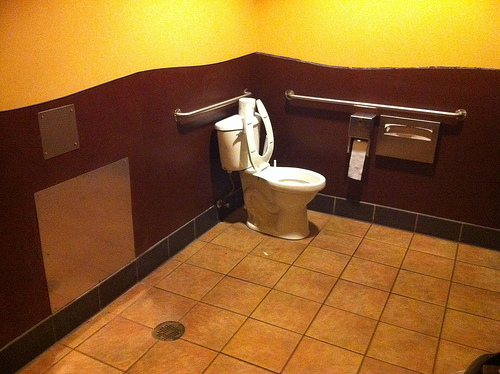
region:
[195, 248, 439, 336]
The floor is made of tile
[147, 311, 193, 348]
The drain in the ground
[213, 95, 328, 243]
The toilet is the color white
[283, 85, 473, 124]
The holding bar on the wall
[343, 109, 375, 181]
The toilet paper dispenser on the wall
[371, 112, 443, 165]
The toilet paper cover holder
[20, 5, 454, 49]
The color of the wall is yellow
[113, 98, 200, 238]
The color of the wall is brown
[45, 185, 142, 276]
The silver plate on the wall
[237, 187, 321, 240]
The bottom of the toilet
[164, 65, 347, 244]
this is a toilet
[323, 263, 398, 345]
this is a tile on the floor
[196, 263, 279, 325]
this is a tile on the floor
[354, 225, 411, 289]
this is a tile on the floor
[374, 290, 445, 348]
this is a tile on the floor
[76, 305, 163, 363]
this is a tile on the floor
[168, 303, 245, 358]
this is a tile on the floor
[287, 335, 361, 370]
this is a tile on the floor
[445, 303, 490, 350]
this is a tile on the floor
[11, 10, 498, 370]
a public restroom has a tiled floor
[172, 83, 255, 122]
a grab bar is above the toilet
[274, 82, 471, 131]
a long grab bar is near the toilet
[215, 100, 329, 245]
the toilet is white porcelain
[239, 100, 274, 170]
the seat is up on the toilet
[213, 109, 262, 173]
the water closet is on the toilet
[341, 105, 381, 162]
a metal toilet paper dispenser is on the wall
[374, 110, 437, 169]
tissue seat liner dispenser is on the wall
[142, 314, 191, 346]
a drain is in the floor of the bathroom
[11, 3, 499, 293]
the walls are painted yellow and brown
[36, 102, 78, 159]
the small petal plate on the wall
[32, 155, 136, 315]
the large metal plate on the wall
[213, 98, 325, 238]
the white toilet bowl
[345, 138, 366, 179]
the toilet paper in the dispenser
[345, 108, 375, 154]
the toilet paper metal dispenser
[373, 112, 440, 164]
the dispenser for toilet seat protector sheets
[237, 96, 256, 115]
the roll of toilet paper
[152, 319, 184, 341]
the drain in the floor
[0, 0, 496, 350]
the two toned bathroom wall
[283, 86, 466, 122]
the long metal bar on the wall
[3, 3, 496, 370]
yellow, brown and tan public bathroom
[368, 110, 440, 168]
stainless steel holder for toilet seat covers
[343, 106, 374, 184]
stainless steel dispenser for toilet paper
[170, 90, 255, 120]
stainless steel grab bar on the wall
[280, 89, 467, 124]
stainless steel grab bar on the wall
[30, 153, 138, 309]
stainless steel plate on a brown wall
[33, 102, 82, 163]
stainless steel plate on a brown wall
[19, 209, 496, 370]
tan and brown flooring tile in a bathroom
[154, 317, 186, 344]
drain in a brown and tan tiled floor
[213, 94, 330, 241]
white toilet on a tiled floor